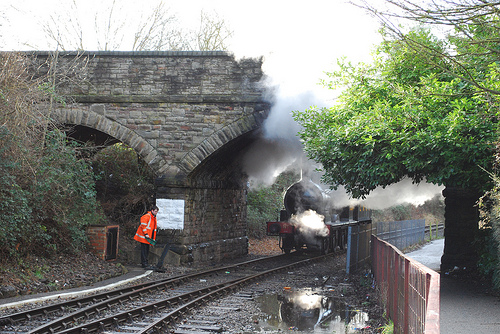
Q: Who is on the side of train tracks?
A: A man.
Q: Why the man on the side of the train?
A: Inspecting.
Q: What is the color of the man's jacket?
A: Orange.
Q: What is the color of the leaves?
A: Green.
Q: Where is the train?
A: On the train tracks.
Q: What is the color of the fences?
A: Blue and red.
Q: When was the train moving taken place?
A: Daytime.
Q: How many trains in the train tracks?
A: One.